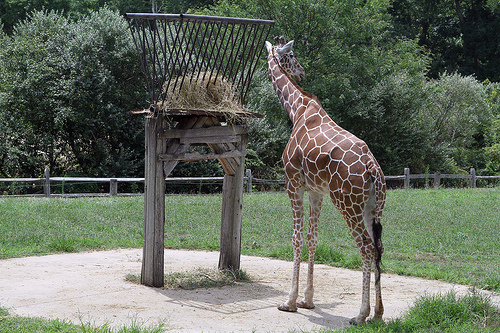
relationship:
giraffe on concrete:
[266, 35, 385, 323] [1, 247, 487, 332]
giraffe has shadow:
[266, 35, 385, 323] [299, 301, 357, 332]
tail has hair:
[370, 164, 383, 283] [372, 218, 382, 284]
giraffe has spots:
[266, 35, 385, 323] [292, 133, 331, 168]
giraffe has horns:
[266, 35, 385, 323] [275, 36, 285, 44]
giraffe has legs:
[266, 35, 385, 323] [276, 181, 384, 323]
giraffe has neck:
[266, 35, 385, 323] [267, 46, 323, 127]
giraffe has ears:
[266, 35, 385, 323] [263, 39, 292, 57]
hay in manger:
[165, 72, 244, 111] [127, 10, 273, 111]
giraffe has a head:
[266, 35, 385, 323] [266, 35, 308, 81]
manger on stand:
[127, 10, 273, 111] [142, 117, 247, 285]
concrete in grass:
[1, 247, 487, 332] [2, 188, 499, 332]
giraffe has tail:
[266, 35, 385, 323] [370, 164, 383, 283]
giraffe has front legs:
[266, 35, 385, 323] [278, 180, 320, 311]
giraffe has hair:
[266, 35, 385, 323] [372, 218, 382, 284]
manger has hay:
[127, 10, 273, 111] [165, 72, 244, 111]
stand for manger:
[142, 117, 247, 285] [127, 10, 273, 111]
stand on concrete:
[142, 117, 247, 285] [1, 247, 487, 332]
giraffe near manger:
[266, 35, 385, 323] [127, 10, 273, 111]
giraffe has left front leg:
[266, 35, 385, 323] [276, 182, 302, 315]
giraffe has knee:
[266, 35, 385, 323] [306, 235, 318, 250]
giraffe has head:
[266, 35, 385, 323] [266, 35, 308, 81]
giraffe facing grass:
[266, 35, 385, 323] [2, 188, 499, 332]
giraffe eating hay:
[266, 35, 385, 323] [165, 72, 244, 111]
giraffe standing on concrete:
[266, 35, 385, 323] [1, 247, 487, 332]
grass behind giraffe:
[2, 188, 499, 332] [266, 35, 385, 323]